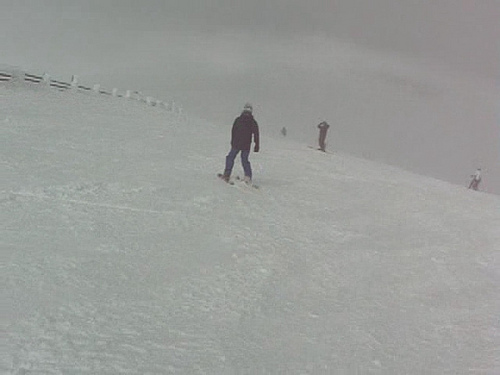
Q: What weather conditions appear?
A: It is cloudy.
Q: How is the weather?
A: It is cloudy.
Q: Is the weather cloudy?
A: Yes, it is cloudy.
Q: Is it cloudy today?
A: Yes, it is cloudy.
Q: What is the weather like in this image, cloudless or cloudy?
A: It is cloudy.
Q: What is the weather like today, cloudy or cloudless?
A: It is cloudy.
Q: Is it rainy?
A: No, it is cloudy.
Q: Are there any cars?
A: No, there are no cars.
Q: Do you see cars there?
A: No, there are no cars.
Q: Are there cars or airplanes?
A: No, there are no cars or airplanes.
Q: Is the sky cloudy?
A: Yes, the sky is cloudy.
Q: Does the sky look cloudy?
A: Yes, the sky is cloudy.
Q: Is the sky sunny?
A: No, the sky is cloudy.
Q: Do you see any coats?
A: Yes, there is a coat.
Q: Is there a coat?
A: Yes, there is a coat.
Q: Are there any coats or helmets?
A: Yes, there is a coat.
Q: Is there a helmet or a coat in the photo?
A: Yes, there is a coat.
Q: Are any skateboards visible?
A: No, there are no skateboards.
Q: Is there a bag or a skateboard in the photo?
A: No, there are no skateboards or bags.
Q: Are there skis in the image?
A: Yes, there are skis.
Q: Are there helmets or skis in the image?
A: Yes, there are skis.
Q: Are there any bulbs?
A: No, there are no bulbs.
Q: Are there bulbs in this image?
A: No, there are no bulbs.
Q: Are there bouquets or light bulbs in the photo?
A: No, there are no light bulbs or bouquets.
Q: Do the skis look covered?
A: Yes, the skis are covered.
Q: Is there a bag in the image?
A: No, there are no bags.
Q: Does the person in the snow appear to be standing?
A: Yes, the person is standing.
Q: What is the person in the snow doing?
A: The person is standing.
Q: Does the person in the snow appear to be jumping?
A: No, the person is standing.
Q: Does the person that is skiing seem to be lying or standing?
A: The person is standing.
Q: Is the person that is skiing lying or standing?
A: The person is standing.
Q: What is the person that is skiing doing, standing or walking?
A: The person is standing.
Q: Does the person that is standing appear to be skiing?
A: Yes, the person is skiing.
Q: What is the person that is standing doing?
A: The person is skiing.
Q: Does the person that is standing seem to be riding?
A: No, the person is skiing.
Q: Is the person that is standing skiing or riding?
A: The person is skiing.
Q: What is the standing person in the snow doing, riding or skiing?
A: The person is skiing.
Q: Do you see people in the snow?
A: Yes, there is a person in the snow.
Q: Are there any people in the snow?
A: Yes, there is a person in the snow.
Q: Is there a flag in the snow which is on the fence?
A: No, there is a person in the snow.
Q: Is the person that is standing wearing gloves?
A: Yes, the person is wearing gloves.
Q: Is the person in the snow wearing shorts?
A: No, the person is wearing gloves.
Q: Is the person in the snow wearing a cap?
A: Yes, the person is wearing a cap.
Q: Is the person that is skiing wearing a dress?
A: No, the person is wearing a cap.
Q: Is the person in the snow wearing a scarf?
A: Yes, the person is wearing a scarf.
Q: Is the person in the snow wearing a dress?
A: No, the person is wearing a scarf.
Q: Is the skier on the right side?
A: Yes, the skier is on the right of the image.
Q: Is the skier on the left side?
A: No, the skier is on the right of the image.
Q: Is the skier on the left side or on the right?
A: The skier is on the right of the image.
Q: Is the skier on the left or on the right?
A: The skier is on the right of the image.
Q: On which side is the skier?
A: The skier is on the right of the image.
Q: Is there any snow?
A: Yes, there is snow.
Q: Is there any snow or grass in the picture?
A: Yes, there is snow.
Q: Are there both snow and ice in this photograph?
A: No, there is snow but no ice.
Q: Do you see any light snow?
A: Yes, there is light snow.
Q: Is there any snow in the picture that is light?
A: Yes, there is snow that is light.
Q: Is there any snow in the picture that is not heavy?
A: Yes, there is light snow.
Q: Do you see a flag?
A: No, there are no flags.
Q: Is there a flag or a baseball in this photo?
A: No, there are no flags or baseballs.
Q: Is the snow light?
A: Yes, the snow is light.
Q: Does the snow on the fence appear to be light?
A: Yes, the snow is light.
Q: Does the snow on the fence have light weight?
A: Yes, the snow is light.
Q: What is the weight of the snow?
A: The snow is light.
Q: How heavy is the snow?
A: The snow is light.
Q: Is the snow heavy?
A: No, the snow is light.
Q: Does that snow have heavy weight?
A: No, the snow is light.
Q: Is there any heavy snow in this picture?
A: No, there is snow but it is light.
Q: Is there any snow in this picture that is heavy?
A: No, there is snow but it is light.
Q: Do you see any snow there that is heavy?
A: No, there is snow but it is light.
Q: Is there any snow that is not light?
A: No, there is snow but it is light.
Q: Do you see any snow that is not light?
A: No, there is snow but it is light.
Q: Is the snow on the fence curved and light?
A: Yes, the snow is curved and light.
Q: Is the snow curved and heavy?
A: No, the snow is curved but light.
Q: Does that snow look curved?
A: Yes, the snow is curved.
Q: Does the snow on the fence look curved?
A: Yes, the snow is curved.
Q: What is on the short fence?
A: The snow is on the fence.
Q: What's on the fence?
A: The snow is on the fence.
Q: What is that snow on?
A: The snow is on the fence.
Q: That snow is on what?
A: The snow is on the fence.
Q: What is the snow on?
A: The snow is on the fence.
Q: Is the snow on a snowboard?
A: No, the snow is on the fence.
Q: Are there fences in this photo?
A: Yes, there is a fence.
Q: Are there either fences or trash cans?
A: Yes, there is a fence.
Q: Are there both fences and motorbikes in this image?
A: No, there is a fence but no motorcycles.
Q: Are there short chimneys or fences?
A: Yes, there is a short fence.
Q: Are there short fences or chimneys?
A: Yes, there is a short fence.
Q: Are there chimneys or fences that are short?
A: Yes, the fence is short.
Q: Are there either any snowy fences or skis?
A: Yes, there is a snowy fence.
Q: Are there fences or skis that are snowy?
A: Yes, the fence is snowy.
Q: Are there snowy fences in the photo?
A: Yes, there is a snowy fence.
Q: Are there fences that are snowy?
A: Yes, there is a fence that is snowy.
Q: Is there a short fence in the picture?
A: Yes, there is a short fence.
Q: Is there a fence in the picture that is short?
A: Yes, there is a fence that is short.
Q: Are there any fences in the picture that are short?
A: Yes, there is a fence that is short.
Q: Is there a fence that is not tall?
A: Yes, there is a short fence.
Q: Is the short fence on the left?
A: Yes, the fence is on the left of the image.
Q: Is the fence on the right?
A: No, the fence is on the left of the image.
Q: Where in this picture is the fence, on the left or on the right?
A: The fence is on the left of the image.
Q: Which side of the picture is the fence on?
A: The fence is on the left of the image.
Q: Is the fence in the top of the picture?
A: Yes, the fence is in the top of the image.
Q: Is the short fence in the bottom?
A: No, the fence is in the top of the image.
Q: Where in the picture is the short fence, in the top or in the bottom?
A: The fence is in the top of the image.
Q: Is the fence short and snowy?
A: Yes, the fence is short and snowy.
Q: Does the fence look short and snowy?
A: Yes, the fence is short and snowy.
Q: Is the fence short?
A: Yes, the fence is short.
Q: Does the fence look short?
A: Yes, the fence is short.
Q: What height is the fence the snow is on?
A: The fence is short.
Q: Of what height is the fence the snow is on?
A: The fence is short.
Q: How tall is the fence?
A: The fence is short.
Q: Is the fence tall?
A: No, the fence is short.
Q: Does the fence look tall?
A: No, the fence is short.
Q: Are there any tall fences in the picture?
A: No, there is a fence but it is short.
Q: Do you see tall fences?
A: No, there is a fence but it is short.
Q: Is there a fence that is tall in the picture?
A: No, there is a fence but it is short.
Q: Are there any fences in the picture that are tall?
A: No, there is a fence but it is short.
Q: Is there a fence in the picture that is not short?
A: No, there is a fence but it is short.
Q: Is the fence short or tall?
A: The fence is short.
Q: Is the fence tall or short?
A: The fence is short.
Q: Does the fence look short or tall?
A: The fence is short.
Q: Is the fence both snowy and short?
A: Yes, the fence is snowy and short.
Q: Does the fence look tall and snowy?
A: No, the fence is snowy but short.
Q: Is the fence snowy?
A: Yes, the fence is snowy.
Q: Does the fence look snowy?
A: Yes, the fence is snowy.